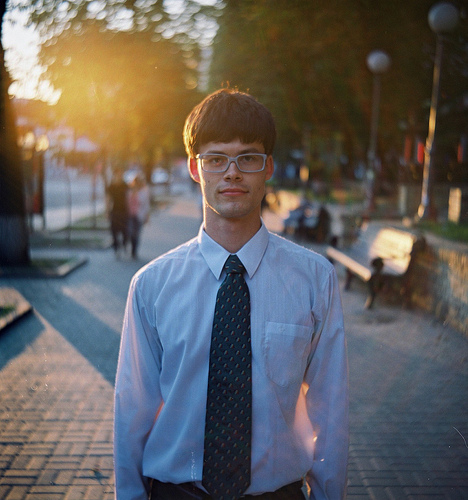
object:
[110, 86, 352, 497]
man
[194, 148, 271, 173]
glasses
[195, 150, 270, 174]
frames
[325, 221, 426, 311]
bench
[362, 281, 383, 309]
legs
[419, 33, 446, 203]
lamppost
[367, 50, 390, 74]
globe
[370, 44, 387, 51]
top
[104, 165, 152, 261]
couple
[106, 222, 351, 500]
shirt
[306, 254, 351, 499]
arms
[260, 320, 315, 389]
pocket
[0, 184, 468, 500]
front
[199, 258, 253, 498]
tie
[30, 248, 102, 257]
sidewalk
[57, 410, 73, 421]
brick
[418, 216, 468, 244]
grass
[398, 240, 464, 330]
wall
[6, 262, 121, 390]
shadow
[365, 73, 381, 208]
lamppost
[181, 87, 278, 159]
hair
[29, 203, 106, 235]
road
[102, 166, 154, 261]
together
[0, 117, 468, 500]
park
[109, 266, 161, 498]
sleeves